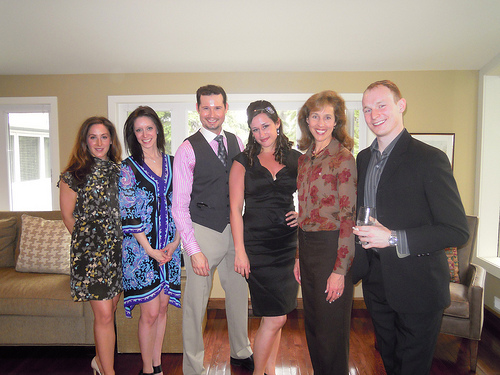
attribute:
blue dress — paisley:
[119, 151, 184, 312]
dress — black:
[227, 142, 306, 328]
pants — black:
[297, 229, 358, 374]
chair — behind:
[382, 201, 484, 371]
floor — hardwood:
[279, 322, 305, 374]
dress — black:
[233, 145, 303, 317]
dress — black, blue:
[112, 149, 183, 314]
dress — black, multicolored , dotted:
[58, 150, 126, 298]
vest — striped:
[183, 125, 249, 233]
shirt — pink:
[154, 124, 250, 261]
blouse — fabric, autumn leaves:
[298, 141, 360, 267]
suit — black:
[355, 128, 470, 374]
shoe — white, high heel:
[84, 356, 104, 373]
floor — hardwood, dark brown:
[40, 227, 482, 354]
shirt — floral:
[277, 141, 361, 240]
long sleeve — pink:
[168, 125, 248, 256]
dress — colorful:
[60, 169, 118, 303]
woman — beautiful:
[113, 111, 186, 373]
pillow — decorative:
[439, 240, 462, 279]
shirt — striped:
[172, 134, 247, 256]